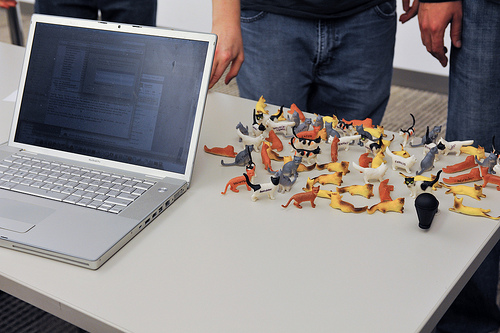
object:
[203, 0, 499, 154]
two people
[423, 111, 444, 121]
patterned tan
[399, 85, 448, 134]
rug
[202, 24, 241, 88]
hands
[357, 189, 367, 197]
yellow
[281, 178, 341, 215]
cats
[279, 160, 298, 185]
grey cat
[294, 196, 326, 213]
legs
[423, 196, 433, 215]
black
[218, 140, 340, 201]
cat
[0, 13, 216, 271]
computer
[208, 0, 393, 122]
man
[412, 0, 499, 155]
man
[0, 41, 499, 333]
table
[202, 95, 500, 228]
cat figurines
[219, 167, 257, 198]
figurine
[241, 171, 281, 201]
figurine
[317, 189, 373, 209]
figurine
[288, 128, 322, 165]
figurines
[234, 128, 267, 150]
figurine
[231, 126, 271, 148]
fur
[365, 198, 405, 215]
action figure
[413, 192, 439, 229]
action figure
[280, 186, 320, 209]
cat figurine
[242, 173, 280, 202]
cat figurine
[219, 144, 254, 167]
cat figurine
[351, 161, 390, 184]
cat figurine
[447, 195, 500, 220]
cat figurine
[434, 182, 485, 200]
cat figurine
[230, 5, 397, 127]
jeans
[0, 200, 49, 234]
mousepad